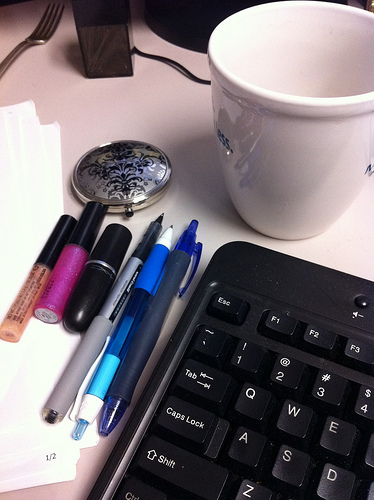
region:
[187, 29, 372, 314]
white cup on desktop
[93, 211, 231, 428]
blue pen next to keyboard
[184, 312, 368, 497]
black keyboard with white characters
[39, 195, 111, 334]
pink and black container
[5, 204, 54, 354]
peach and black container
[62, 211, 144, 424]
black and gray pen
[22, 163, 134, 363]
white paper under items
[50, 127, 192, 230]
silver and black design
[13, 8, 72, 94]
fork laying on desktop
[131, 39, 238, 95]
black cord on desktop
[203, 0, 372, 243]
A white cup is on the desk.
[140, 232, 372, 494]
A keyboard is in the corner.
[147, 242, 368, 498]
The keyboard is black.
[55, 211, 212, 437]
Three ink pens.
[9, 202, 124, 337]
A bottle of nail polish.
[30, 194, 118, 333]
The nail polish is pink.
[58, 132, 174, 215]
A pocket watch.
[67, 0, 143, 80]
A box of paper clips.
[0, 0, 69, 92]
A fork is in the corner.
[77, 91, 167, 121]
The table is white.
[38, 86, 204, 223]
silver compact mirror with design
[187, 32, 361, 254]
white coffee mug on table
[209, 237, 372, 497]
black keyboard with white letters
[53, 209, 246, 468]
three pens next to keyboard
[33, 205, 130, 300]
three lip glosses on table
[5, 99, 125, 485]
pile of white paperwork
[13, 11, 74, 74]
metal fork on table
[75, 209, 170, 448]
black, blue and grey pens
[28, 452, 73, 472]
black numbers on white paper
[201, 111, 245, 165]
blue writing on white coffee mug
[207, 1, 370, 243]
empty white coffee mug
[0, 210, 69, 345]
tube of peach lip gloss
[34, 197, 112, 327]
tube of fuscia lip gloss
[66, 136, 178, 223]
silver pocket watch with embossing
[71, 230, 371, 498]
top left edge of black keyboard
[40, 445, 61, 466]
"1/2" on bottom corner of page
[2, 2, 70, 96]
clean silver fork on desk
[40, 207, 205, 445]
3 ink pens in various colors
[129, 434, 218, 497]
black and white shift key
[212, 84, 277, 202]
reflection of pens on cup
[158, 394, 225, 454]
the caps lock button on the keyboard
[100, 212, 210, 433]
a blue pen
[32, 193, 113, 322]
pink lipgloss on the counter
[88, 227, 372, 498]
part of a keyboard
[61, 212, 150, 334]
a small black lipstick container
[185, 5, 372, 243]
an empty white coffee cup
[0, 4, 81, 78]
a fork on the table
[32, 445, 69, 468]
numbers on a white piece of paper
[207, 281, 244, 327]
the escape button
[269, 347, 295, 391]
the number two